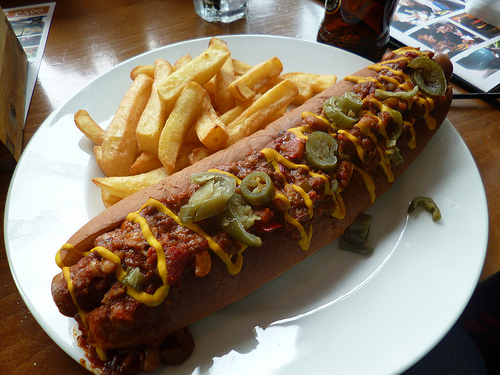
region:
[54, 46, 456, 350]
a gigantic hot dog on a bun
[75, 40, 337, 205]
stack of golden french fries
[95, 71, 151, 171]
single golden french fry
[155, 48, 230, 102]
single golden french fry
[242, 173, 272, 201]
slice of jalapeno pepper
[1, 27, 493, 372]
round white plate on table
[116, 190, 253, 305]
mustard on hot dog on plate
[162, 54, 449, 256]
green peppers on top of hot dog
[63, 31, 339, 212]
french fries on plate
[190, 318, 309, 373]
white light reflected on plate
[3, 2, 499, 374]
wooden table underneath plate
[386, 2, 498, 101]
magazine on wooden table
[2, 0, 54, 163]
box on floor near table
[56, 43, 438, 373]
chili on hot dog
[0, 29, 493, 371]
a big hot dog on a white dish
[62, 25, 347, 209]
potatoes on side a dish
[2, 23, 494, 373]
hot dog has green chili pepper on top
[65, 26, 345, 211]
potato are golden fried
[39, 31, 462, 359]
mustard on top of hot dog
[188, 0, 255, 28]
a glass on top a table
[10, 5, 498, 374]
a dish on a brown surface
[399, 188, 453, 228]
green chili pepper on dish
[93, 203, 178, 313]
the mustard is yellow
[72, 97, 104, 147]
fry on a plate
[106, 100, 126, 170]
fry on a plate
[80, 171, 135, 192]
fry on a plate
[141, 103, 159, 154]
fry on a plate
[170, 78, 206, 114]
fry on a plate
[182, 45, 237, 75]
fry on a plate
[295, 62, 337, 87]
fry on a plate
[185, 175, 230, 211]
pepper on a hot dog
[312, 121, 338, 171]
pepper on a hot dog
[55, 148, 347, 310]
a hotdog that is cooked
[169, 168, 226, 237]
a slice jalpeno on hotdog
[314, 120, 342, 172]
a slice jalpeno on hotdog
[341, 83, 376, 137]
a slice jalpeno on hotdog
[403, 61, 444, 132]
a slice jalpeno on hotdog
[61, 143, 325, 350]
a long hotdog on plate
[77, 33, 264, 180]
cooked french fries on plate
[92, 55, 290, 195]
cooked french fries on white plate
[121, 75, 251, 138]
golden fries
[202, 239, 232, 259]
the mustard is yellow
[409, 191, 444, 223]
a pickle on the plate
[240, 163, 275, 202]
A piece of food.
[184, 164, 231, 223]
A piece of food.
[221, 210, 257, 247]
A piece of food.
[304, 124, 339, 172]
A piece of food.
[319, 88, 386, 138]
A piece of food.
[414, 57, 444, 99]
A piece of food.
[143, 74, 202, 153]
A piece of food.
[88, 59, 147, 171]
A piece of food.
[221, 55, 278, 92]
A piece of food.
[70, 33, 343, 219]
french fries on white plate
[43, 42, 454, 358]
long hot dog on plate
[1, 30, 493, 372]
round white plate holding food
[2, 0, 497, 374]
wooden table underneath plate of food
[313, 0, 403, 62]
bottom of brown beverage bottle on table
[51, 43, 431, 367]
mustard drizzled on hot dog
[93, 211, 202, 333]
red sauce on top of hot dog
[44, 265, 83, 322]
tip of hotdog at end of bun